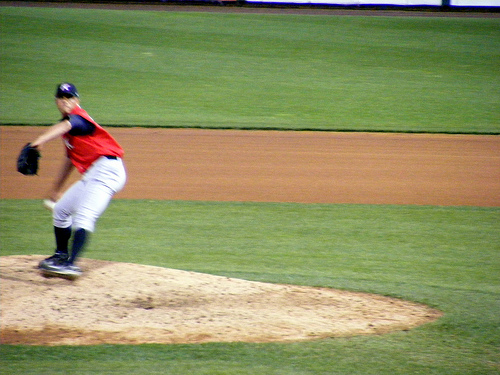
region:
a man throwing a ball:
[10, 41, 142, 291]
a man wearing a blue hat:
[53, 67, 85, 107]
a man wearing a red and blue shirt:
[54, 89, 112, 174]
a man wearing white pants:
[62, 147, 126, 227]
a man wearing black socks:
[47, 205, 89, 272]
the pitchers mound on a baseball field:
[2, 240, 179, 350]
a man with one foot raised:
[56, 245, 91, 287]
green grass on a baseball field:
[122, 29, 435, 104]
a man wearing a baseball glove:
[14, 136, 47, 178]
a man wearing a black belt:
[106, 145, 129, 168]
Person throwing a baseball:
[13, 81, 130, 283]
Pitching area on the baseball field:
[0, 249, 441, 347]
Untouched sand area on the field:
[0, 124, 495, 204]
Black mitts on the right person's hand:
[15, 142, 43, 177]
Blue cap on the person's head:
[52, 81, 78, 96]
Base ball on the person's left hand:
[44, 196, 57, 209]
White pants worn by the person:
[49, 154, 126, 233]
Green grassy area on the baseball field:
[0, 4, 498, 134]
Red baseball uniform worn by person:
[60, 103, 127, 175]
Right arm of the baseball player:
[25, 119, 73, 146]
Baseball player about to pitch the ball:
[8, 79, 131, 279]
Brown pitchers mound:
[1, 254, 429, 351]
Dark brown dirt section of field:
[2, 119, 497, 214]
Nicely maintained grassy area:
[3, 9, 498, 122]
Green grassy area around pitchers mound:
[1, 200, 498, 372]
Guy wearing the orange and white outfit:
[15, 84, 131, 279]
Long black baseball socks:
[43, 222, 100, 266]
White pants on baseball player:
[42, 150, 134, 232]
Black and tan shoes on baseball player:
[36, 253, 80, 278]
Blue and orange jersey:
[51, 107, 123, 169]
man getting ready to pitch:
[29, 78, 134, 267]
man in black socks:
[47, 215, 89, 270]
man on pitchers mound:
[78, 290, 128, 313]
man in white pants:
[70, 195, 96, 208]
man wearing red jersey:
[70, 118, 104, 151]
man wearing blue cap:
[48, 79, 81, 95]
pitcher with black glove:
[23, 153, 52, 193]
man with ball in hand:
[28, 181, 67, 208]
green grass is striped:
[192, 86, 223, 90]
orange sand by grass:
[264, 150, 267, 160]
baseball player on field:
[25, 75, 172, 282]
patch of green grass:
[288, 247, 325, 271]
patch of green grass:
[453, 276, 480, 302]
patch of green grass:
[383, 345, 416, 361]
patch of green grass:
[311, 348, 342, 363]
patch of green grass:
[299, 250, 318, 265]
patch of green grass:
[259, 209, 292, 229]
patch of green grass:
[419, 231, 448, 253]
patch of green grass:
[226, 232, 246, 254]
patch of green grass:
[146, 225, 186, 243]